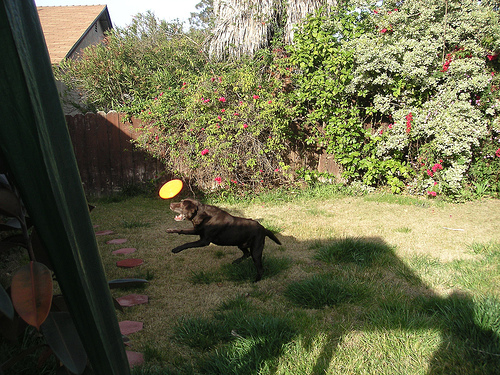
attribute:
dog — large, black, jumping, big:
[156, 192, 280, 283]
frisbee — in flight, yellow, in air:
[150, 174, 189, 204]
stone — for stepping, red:
[116, 256, 147, 272]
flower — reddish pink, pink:
[196, 145, 213, 158]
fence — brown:
[56, 99, 396, 207]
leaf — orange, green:
[10, 256, 55, 329]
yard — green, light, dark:
[87, 189, 500, 373]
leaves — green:
[284, 18, 404, 184]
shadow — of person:
[430, 287, 497, 372]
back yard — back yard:
[8, 83, 498, 374]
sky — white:
[33, 1, 209, 34]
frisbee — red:
[119, 257, 141, 269]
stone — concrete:
[110, 275, 152, 290]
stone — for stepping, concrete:
[117, 288, 150, 307]